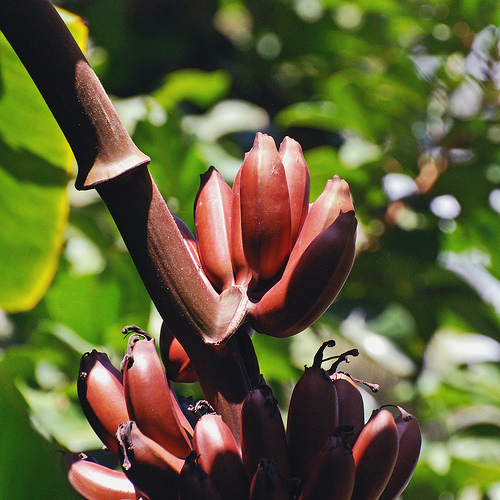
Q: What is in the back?
A: Leafs.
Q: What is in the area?
A: Leaves.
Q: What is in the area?
A: Fruit.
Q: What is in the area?
A: Sun shine.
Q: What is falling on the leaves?
A: Light.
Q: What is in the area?
A: Shadow.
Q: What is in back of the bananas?
A: Leaves.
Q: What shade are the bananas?
A: Red.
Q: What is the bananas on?
A: Brown stem.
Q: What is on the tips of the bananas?
A: Stems.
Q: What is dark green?
A: Leaves.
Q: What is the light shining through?
A: Leaves.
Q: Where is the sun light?
A: Hitting the red bananas.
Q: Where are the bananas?
A: Attached to a thick stem.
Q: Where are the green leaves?
A: Behind the bananas.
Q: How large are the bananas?
A: Small.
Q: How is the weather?
A: Sunny.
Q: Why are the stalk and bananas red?
A: The plant is a red banana plant.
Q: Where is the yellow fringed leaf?
A: Behind the stalk.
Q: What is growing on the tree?
A: Bananas.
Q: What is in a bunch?
A: Bananas.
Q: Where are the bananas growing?
A: On a tree.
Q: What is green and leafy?
A: Branches.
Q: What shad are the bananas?
A: Red.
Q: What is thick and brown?
A: The stem.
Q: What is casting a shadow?
A: The banana tree.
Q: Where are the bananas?
A: On a tree.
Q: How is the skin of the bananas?
A: Smooth.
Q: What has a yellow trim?
A: The leaf.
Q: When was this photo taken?
A: Daytime.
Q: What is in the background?
A: Green leaves.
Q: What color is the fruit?
A: Brownish red.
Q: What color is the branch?
A: Brown.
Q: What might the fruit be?
A: Bananas.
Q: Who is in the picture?
A: No one.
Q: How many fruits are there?
A: 21.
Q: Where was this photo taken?
A: In a forest.